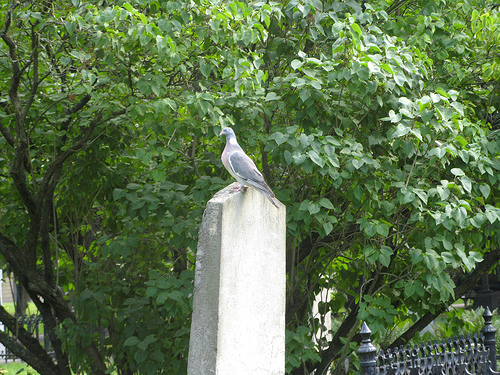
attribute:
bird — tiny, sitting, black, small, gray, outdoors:
[209, 115, 272, 180]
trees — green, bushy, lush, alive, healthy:
[275, 19, 462, 172]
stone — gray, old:
[203, 206, 290, 373]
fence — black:
[359, 327, 500, 368]